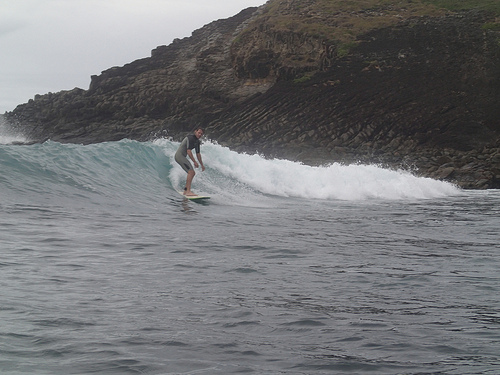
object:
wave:
[315, 163, 457, 221]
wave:
[252, 146, 311, 190]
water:
[231, 223, 341, 304]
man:
[173, 126, 207, 196]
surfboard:
[182, 190, 214, 200]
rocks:
[381, 119, 469, 152]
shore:
[211, 103, 355, 168]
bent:
[172, 143, 185, 161]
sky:
[0, 0, 267, 115]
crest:
[226, 144, 258, 171]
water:
[1, 125, 34, 147]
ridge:
[94, 57, 144, 86]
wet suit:
[173, 134, 201, 174]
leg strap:
[182, 186, 187, 191]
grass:
[316, 19, 360, 41]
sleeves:
[183, 135, 192, 152]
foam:
[246, 159, 291, 187]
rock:
[250, 76, 327, 150]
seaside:
[260, 144, 397, 174]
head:
[193, 124, 206, 138]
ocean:
[261, 182, 400, 256]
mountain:
[0, 1, 499, 189]